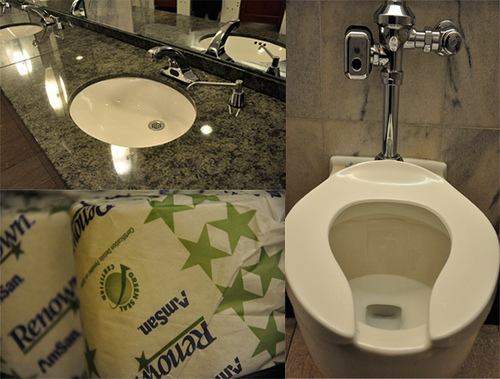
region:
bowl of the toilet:
[373, 280, 426, 323]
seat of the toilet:
[315, 223, 362, 325]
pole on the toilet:
[390, 46, 395, 156]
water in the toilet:
[377, 280, 400, 290]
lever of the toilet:
[442, 23, 459, 77]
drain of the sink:
[100, 97, 168, 137]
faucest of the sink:
[202, 79, 247, 109]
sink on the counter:
[29, 46, 213, 154]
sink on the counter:
[6, 22, 40, 50]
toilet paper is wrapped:
[102, 199, 235, 357]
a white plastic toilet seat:
[283, 155, 499, 347]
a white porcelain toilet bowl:
[290, 155, 488, 377]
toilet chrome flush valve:
[339, 7, 463, 159]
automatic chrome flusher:
[344, 27, 371, 82]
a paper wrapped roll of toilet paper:
[64, 195, 282, 376]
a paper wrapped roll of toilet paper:
[0, 194, 87, 376]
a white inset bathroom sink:
[69, 75, 196, 147]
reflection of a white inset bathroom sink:
[0, 22, 42, 35]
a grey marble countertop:
[0, 33, 285, 188]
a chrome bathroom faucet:
[142, 44, 198, 86]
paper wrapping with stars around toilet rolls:
[6, 190, 284, 375]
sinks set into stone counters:
[2, 0, 282, 186]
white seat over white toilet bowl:
[289, 90, 498, 372]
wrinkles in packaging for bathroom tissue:
[77, 200, 284, 371]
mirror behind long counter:
[8, 1, 284, 88]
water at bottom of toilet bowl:
[328, 200, 449, 336]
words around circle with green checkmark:
[92, 254, 144, 315]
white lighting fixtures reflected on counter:
[4, 13, 180, 181]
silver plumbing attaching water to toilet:
[342, 5, 465, 161]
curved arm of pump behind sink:
[162, 65, 252, 116]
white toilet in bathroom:
[281, 121, 498, 377]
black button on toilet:
[348, 52, 365, 73]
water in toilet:
[348, 255, 435, 339]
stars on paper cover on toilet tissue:
[168, 217, 238, 280]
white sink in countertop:
[56, 63, 206, 156]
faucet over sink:
[137, 34, 199, 90]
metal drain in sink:
[145, 111, 168, 136]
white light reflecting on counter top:
[197, 113, 218, 139]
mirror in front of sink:
[41, 0, 291, 88]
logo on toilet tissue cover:
[90, 257, 145, 319]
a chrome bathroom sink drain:
[147, 118, 164, 130]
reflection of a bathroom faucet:
[205, 17, 245, 59]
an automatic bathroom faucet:
[145, 45, 200, 80]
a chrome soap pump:
[180, 80, 245, 107]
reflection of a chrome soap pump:
[253, 40, 279, 75]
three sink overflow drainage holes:
[252, 40, 268, 47]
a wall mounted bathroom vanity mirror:
[93, 0, 285, 82]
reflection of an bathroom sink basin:
[1, 24, 41, 41]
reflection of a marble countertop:
[115, 8, 286, 75]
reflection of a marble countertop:
[1, 1, 98, 64]